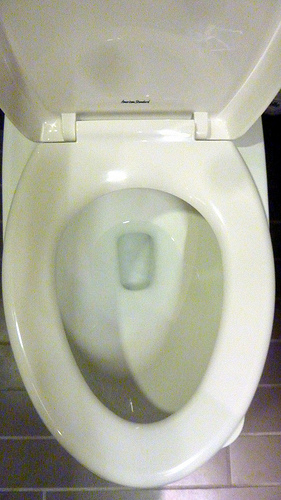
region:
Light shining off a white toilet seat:
[145, 440, 238, 486]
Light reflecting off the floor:
[178, 442, 241, 498]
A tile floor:
[3, 419, 60, 498]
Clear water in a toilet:
[83, 213, 194, 325]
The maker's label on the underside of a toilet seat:
[109, 88, 165, 108]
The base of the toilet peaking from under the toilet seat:
[218, 408, 251, 459]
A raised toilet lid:
[5, 10, 272, 152]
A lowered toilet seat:
[37, 338, 235, 479]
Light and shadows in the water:
[82, 188, 200, 351]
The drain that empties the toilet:
[107, 224, 175, 294]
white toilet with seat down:
[12, 65, 258, 356]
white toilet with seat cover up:
[16, 20, 255, 151]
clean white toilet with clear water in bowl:
[12, 131, 257, 442]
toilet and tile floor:
[9, 370, 263, 490]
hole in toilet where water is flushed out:
[100, 230, 170, 303]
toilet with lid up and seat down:
[10, 62, 255, 376]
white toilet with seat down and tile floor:
[6, 185, 252, 491]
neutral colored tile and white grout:
[8, 413, 65, 495]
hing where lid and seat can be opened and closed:
[24, 110, 229, 160]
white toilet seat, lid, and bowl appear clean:
[11, 21, 243, 302]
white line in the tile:
[14, 433, 45, 443]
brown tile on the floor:
[241, 451, 269, 478]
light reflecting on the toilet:
[172, 457, 205, 467]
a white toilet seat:
[19, 296, 49, 363]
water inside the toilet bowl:
[157, 226, 174, 258]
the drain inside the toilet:
[123, 246, 146, 281]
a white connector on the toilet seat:
[58, 112, 76, 140]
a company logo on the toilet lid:
[120, 94, 155, 107]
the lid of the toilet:
[30, 13, 237, 82]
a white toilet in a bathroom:
[5, 10, 267, 480]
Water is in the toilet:
[86, 218, 236, 388]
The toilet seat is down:
[2, 241, 269, 498]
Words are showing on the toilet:
[115, 89, 190, 116]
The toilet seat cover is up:
[31, 5, 280, 153]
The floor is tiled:
[8, 376, 269, 496]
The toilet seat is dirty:
[3, 154, 158, 302]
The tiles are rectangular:
[0, 373, 267, 490]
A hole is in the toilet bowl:
[109, 227, 203, 317]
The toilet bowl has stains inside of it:
[59, 266, 206, 413]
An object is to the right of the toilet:
[260, 87, 279, 120]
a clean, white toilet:
[0, 0, 280, 488]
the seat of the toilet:
[0, 120, 274, 486]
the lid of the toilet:
[1, 0, 280, 142]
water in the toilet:
[85, 217, 185, 339]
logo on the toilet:
[121, 99, 150, 103]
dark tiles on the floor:
[1, 292, 279, 498]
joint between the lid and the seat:
[60, 112, 208, 138]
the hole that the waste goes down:
[116, 231, 154, 292]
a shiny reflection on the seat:
[106, 127, 191, 179]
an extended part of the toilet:
[218, 415, 244, 446]